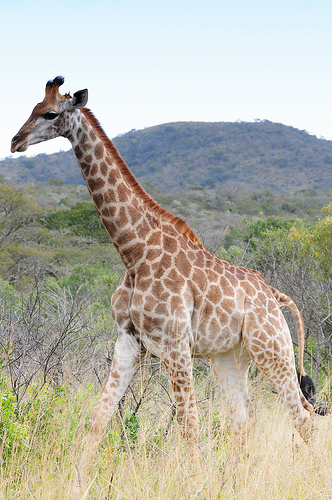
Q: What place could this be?
A: It is a meadow.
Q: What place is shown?
A: It is a meadow.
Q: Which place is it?
A: It is a meadow.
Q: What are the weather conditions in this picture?
A: It is clear.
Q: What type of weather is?
A: It is clear.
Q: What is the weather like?
A: It is clear.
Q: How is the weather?
A: It is clear.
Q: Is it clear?
A: Yes, it is clear.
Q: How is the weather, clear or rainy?
A: It is clear.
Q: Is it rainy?
A: No, it is clear.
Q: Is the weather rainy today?
A: No, it is clear.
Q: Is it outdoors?
A: Yes, it is outdoors.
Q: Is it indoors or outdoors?
A: It is outdoors.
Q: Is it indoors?
A: No, it is outdoors.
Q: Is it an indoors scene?
A: No, it is outdoors.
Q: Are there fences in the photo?
A: No, there are no fences.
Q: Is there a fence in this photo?
A: No, there are no fences.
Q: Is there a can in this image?
A: No, there are no cans.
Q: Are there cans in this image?
A: No, there are no cans.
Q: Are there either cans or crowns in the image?
A: No, there are no cans or crowns.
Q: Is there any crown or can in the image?
A: No, there are no cans or crowns.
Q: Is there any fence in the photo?
A: No, there are no fences.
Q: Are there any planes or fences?
A: No, there are no fences or planes.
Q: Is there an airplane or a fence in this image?
A: No, there are no fences or airplanes.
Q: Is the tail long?
A: Yes, the tail is long.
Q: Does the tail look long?
A: Yes, the tail is long.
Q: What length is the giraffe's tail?
A: The tail is long.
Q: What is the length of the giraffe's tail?
A: The tail is long.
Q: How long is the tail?
A: The tail is long.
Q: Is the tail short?
A: No, the tail is long.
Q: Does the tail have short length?
A: No, the tail is long.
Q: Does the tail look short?
A: No, the tail is long.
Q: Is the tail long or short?
A: The tail is long.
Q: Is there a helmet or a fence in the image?
A: No, there are no fences or helmets.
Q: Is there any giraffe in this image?
A: Yes, there is a giraffe.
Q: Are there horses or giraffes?
A: Yes, there is a giraffe.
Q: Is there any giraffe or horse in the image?
A: Yes, there is a giraffe.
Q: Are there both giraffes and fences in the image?
A: No, there is a giraffe but no fences.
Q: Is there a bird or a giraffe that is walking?
A: Yes, the giraffe is walking.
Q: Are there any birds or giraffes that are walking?
A: Yes, the giraffe is walking.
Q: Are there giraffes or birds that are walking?
A: Yes, the giraffe is walking.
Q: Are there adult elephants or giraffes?
A: Yes, there is an adult giraffe.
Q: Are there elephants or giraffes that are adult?
A: Yes, the giraffe is adult.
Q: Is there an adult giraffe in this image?
A: Yes, there is an adult giraffe.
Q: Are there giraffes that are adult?
A: Yes, there is a giraffe that is adult.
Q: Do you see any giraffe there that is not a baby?
A: Yes, there is a adult giraffe.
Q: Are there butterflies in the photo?
A: No, there are no butterflies.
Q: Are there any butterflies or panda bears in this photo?
A: No, there are no butterflies or panda bears.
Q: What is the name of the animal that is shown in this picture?
A: The animal is a giraffe.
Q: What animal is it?
A: The animal is a giraffe.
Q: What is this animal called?
A: This is a giraffe.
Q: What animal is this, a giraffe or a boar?
A: This is a giraffe.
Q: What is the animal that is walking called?
A: The animal is a giraffe.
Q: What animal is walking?
A: The animal is a giraffe.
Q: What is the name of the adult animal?
A: The animal is a giraffe.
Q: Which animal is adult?
A: The animal is a giraffe.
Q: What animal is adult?
A: The animal is a giraffe.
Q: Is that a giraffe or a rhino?
A: That is a giraffe.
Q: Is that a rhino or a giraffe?
A: That is a giraffe.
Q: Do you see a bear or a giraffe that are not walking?
A: No, there is a giraffe but it is walking.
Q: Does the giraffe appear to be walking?
A: Yes, the giraffe is walking.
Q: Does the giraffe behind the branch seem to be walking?
A: Yes, the giraffe is walking.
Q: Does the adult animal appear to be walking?
A: Yes, the giraffe is walking.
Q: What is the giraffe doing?
A: The giraffe is walking.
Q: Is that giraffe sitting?
A: No, the giraffe is walking.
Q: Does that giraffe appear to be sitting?
A: No, the giraffe is walking.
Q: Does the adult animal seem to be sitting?
A: No, the giraffe is walking.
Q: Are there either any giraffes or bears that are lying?
A: No, there is a giraffe but it is walking.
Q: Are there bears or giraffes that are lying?
A: No, there is a giraffe but it is walking.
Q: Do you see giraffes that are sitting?
A: No, there is a giraffe but it is walking.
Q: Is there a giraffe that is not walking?
A: No, there is a giraffe but it is walking.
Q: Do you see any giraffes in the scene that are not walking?
A: No, there is a giraffe but it is walking.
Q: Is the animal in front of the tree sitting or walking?
A: The giraffe is walking.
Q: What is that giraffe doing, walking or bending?
A: The giraffe is walking.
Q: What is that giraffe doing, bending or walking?
A: The giraffe is walking.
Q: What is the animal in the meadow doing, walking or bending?
A: The giraffe is walking.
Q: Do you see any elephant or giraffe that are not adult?
A: No, there is a giraffe but it is adult.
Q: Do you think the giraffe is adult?
A: Yes, the giraffe is adult.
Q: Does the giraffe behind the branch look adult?
A: Yes, the giraffe is adult.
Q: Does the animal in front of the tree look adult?
A: Yes, the giraffe is adult.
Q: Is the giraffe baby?
A: No, the giraffe is adult.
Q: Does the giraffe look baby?
A: No, the giraffe is adult.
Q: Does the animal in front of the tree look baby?
A: No, the giraffe is adult.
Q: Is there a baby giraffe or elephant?
A: No, there is a giraffe but it is adult.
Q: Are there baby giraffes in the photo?
A: No, there is a giraffe but it is adult.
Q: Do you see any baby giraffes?
A: No, there is a giraffe but it is adult.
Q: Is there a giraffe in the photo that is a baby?
A: No, there is a giraffe but it is adult.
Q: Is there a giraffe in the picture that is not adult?
A: No, there is a giraffe but it is adult.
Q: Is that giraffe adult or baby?
A: The giraffe is adult.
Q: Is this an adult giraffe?
A: Yes, this is an adult giraffe.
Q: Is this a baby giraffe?
A: No, this is an adult giraffe.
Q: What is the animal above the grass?
A: The animal is a giraffe.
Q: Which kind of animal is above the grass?
A: The animal is a giraffe.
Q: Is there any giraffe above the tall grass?
A: Yes, there is a giraffe above the grass.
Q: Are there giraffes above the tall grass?
A: Yes, there is a giraffe above the grass.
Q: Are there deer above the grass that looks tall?
A: No, there is a giraffe above the grass.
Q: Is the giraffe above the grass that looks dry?
A: Yes, the giraffe is above the grass.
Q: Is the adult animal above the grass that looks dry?
A: Yes, the giraffe is above the grass.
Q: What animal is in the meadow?
A: The giraffe is in the meadow.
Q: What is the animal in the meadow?
A: The animal is a giraffe.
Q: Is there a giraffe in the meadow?
A: Yes, there is a giraffe in the meadow.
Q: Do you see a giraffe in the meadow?
A: Yes, there is a giraffe in the meadow.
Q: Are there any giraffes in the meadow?
A: Yes, there is a giraffe in the meadow.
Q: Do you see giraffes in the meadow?
A: Yes, there is a giraffe in the meadow.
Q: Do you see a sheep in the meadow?
A: No, there is a giraffe in the meadow.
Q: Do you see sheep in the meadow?
A: No, there is a giraffe in the meadow.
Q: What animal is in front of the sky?
A: The giraffe is in front of the sky.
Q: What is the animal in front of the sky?
A: The animal is a giraffe.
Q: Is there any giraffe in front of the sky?
A: Yes, there is a giraffe in front of the sky.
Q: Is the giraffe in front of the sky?
A: Yes, the giraffe is in front of the sky.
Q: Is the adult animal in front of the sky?
A: Yes, the giraffe is in front of the sky.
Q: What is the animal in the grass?
A: The animal is a giraffe.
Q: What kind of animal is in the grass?
A: The animal is a giraffe.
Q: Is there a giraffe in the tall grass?
A: Yes, there is a giraffe in the grass.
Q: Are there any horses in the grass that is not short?
A: No, there is a giraffe in the grass.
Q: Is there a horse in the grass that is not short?
A: No, there is a giraffe in the grass.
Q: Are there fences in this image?
A: No, there are no fences.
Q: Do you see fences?
A: No, there are no fences.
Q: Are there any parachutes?
A: No, there are no parachutes.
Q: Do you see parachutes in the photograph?
A: No, there are no parachutes.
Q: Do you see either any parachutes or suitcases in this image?
A: No, there are no parachutes or suitcases.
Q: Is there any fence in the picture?
A: No, there are no fences.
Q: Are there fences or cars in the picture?
A: No, there are no fences or cars.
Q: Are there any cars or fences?
A: No, there are no fences or cars.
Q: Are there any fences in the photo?
A: No, there are no fences.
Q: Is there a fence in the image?
A: No, there are no fences.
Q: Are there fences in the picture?
A: No, there are no fences.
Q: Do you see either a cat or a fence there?
A: No, there are no fences or cats.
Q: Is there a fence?
A: No, there are no fences.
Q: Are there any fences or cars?
A: No, there are no fences or cars.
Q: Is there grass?
A: Yes, there is grass.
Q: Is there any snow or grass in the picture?
A: Yes, there is grass.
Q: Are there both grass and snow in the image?
A: No, there is grass but no snow.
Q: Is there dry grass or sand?
A: Yes, there is dry grass.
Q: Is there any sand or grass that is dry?
A: Yes, the grass is dry.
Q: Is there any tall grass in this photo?
A: Yes, there is tall grass.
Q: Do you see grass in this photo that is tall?
A: Yes, there is grass that is tall.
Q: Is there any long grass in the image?
A: Yes, there is long grass.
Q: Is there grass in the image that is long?
A: Yes, there is grass that is long.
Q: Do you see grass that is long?
A: Yes, there is grass that is long.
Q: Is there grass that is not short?
A: Yes, there is long grass.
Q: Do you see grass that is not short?
A: Yes, there is long grass.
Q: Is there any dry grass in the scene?
A: Yes, there is dry grass.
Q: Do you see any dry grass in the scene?
A: Yes, there is dry grass.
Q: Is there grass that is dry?
A: Yes, there is grass that is dry.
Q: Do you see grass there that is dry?
A: Yes, there is grass that is dry.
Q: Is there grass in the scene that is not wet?
A: Yes, there is dry grass.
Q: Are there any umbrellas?
A: No, there are no umbrellas.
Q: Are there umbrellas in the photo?
A: No, there are no umbrellas.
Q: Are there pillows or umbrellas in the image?
A: No, there are no umbrellas or pillows.